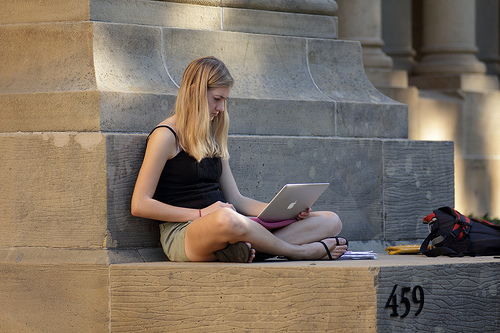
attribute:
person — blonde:
[129, 59, 249, 259]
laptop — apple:
[282, 179, 321, 213]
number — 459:
[386, 277, 429, 321]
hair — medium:
[188, 58, 211, 138]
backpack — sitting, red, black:
[426, 203, 490, 256]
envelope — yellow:
[378, 244, 417, 255]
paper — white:
[346, 246, 376, 263]